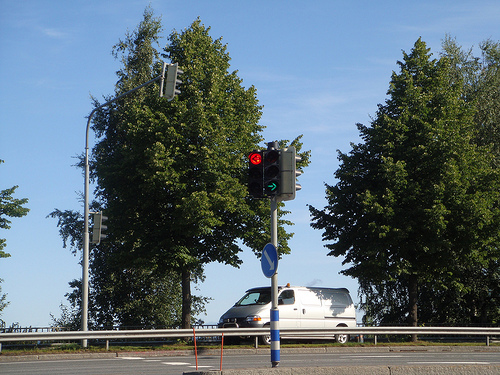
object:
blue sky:
[1, 0, 498, 331]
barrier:
[0, 316, 499, 338]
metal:
[3, 326, 496, 342]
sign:
[259, 241, 279, 276]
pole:
[79, 136, 94, 351]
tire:
[261, 323, 275, 344]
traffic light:
[159, 60, 178, 99]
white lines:
[118, 352, 210, 372]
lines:
[115, 315, 496, 365]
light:
[247, 149, 265, 165]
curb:
[284, 339, 394, 355]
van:
[211, 277, 358, 345]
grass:
[0, 337, 498, 353]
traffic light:
[246, 150, 263, 167]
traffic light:
[244, 146, 296, 203]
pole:
[268, 205, 281, 369]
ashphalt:
[0, 348, 499, 374]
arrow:
[264, 182, 277, 192]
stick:
[189, 321, 202, 373]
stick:
[214, 325, 229, 373]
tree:
[88, 6, 312, 337]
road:
[2, 341, 499, 374]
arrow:
[260, 241, 281, 277]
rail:
[0, 323, 498, 352]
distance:
[6, 10, 498, 340]